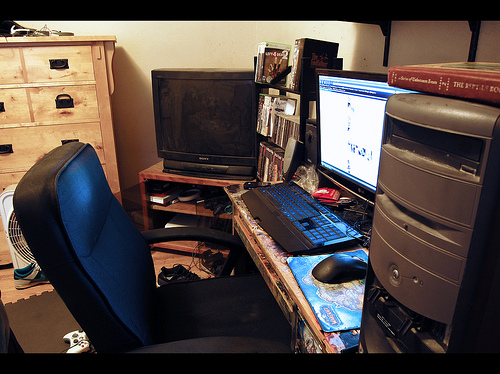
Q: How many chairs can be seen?
A: One.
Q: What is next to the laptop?
A: A book-case.